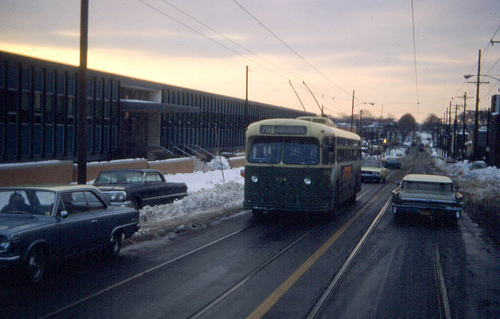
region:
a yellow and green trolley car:
[237, 112, 364, 226]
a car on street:
[0, 175, 140, 278]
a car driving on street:
[385, 167, 462, 228]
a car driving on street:
[352, 157, 389, 183]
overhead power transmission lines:
[179, 18, 386, 130]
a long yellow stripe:
[242, 159, 403, 313]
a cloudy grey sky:
[0, 2, 494, 127]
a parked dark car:
[82, 164, 185, 209]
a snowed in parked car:
[73, 167, 190, 206]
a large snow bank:
[139, 177, 244, 232]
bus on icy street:
[236, 107, 368, 213]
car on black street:
[385, 161, 462, 225]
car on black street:
[0, 189, 140, 287]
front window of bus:
[286, 138, 316, 165]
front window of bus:
[248, 138, 276, 162]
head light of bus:
[300, 172, 312, 189]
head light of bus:
[246, 172, 260, 184]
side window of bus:
[316, 140, 330, 166]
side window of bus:
[326, 139, 336, 160]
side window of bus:
[336, 142, 349, 163]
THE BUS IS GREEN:
[227, 107, 372, 213]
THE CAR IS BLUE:
[392, 178, 462, 220]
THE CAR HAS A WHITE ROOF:
[395, 170, 462, 192]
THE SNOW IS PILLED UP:
[66, 157, 256, 234]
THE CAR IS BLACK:
[90, 162, 197, 212]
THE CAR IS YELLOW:
[346, 157, 393, 185]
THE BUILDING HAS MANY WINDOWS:
[1, 77, 268, 138]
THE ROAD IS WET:
[4, 127, 499, 317]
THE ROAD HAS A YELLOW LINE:
[243, 166, 413, 316]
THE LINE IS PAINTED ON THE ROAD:
[216, 167, 415, 317]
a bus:
[233, 95, 383, 215]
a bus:
[268, 67, 439, 257]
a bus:
[204, 53, 359, 307]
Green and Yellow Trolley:
[239, 99, 390, 231]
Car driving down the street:
[390, 163, 470, 242]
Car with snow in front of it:
[97, 165, 209, 215]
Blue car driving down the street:
[21, 169, 143, 269]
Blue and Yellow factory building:
[24, 72, 238, 148]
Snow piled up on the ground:
[172, 167, 234, 201]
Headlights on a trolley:
[250, 170, 315, 191]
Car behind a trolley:
[366, 155, 385, 190]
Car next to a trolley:
[391, 168, 472, 222]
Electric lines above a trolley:
[192, 30, 384, 115]